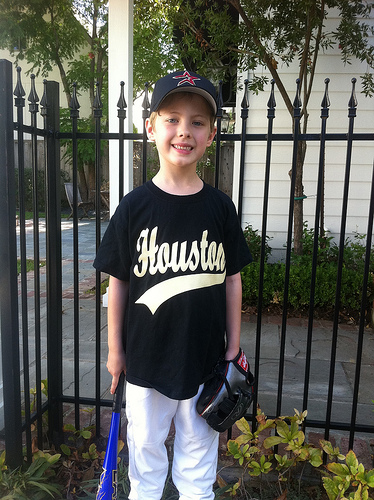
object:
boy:
[91, 66, 259, 498]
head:
[142, 63, 221, 171]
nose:
[176, 121, 192, 138]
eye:
[192, 121, 205, 128]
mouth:
[168, 142, 196, 155]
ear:
[143, 116, 155, 142]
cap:
[149, 67, 222, 125]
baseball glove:
[194, 347, 258, 436]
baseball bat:
[91, 367, 126, 500]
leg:
[123, 380, 171, 500]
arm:
[215, 191, 243, 352]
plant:
[212, 406, 374, 500]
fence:
[0, 54, 374, 476]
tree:
[162, 1, 373, 263]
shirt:
[92, 178, 255, 402]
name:
[132, 223, 227, 317]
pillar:
[106, 0, 135, 221]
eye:
[166, 118, 179, 124]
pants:
[124, 374, 222, 499]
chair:
[62, 180, 94, 223]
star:
[172, 69, 202, 87]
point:
[241, 78, 253, 109]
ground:
[0, 218, 373, 500]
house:
[228, 0, 374, 268]